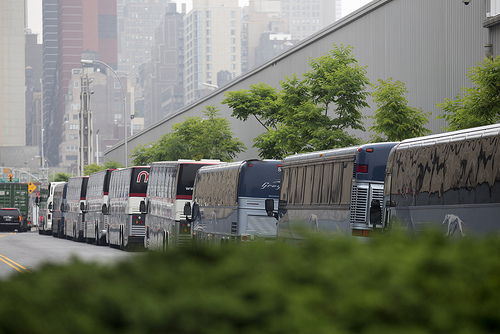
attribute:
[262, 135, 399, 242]
bus — parked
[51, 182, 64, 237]
bus — large, Greyhound, parked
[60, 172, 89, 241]
bus — Greyhound, large, parked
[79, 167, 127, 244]
bus — Greyhound, large, parked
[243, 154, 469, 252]
bus — Greyhound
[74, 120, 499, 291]
bus — blue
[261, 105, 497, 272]
bus — parked, Greyhound, large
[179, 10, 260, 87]
building — large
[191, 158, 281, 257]
bus — blue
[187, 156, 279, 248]
bus — large, Greyhound, parked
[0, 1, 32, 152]
building — brown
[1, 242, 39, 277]
line — yellow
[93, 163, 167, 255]
bus — parked, large, Greyhound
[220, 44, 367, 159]
tree — green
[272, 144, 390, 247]
greyhound bus — parked, large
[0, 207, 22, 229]
suv — black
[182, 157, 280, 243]
bus — parked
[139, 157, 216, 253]
bus — parked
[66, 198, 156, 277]
line — yellow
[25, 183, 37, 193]
sign — yellow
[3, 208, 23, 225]
car — black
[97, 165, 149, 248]
bus — parked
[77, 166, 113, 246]
bus — parked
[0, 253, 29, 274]
line — yellow